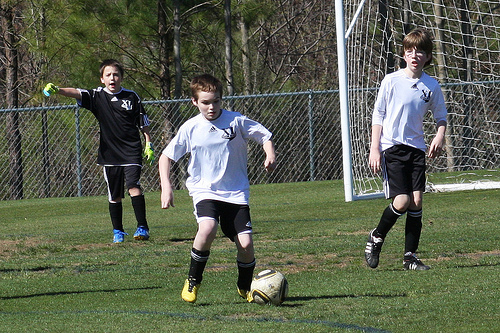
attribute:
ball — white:
[245, 265, 289, 306]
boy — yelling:
[168, 83, 286, 305]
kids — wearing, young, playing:
[65, 34, 455, 313]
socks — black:
[196, 240, 250, 292]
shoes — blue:
[97, 219, 156, 250]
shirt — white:
[162, 120, 268, 214]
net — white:
[347, 5, 498, 191]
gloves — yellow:
[38, 76, 68, 109]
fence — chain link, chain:
[19, 97, 346, 190]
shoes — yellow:
[178, 277, 259, 316]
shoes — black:
[353, 234, 433, 282]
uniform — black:
[81, 83, 169, 252]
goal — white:
[337, 10, 499, 201]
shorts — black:
[98, 164, 150, 199]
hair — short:
[190, 78, 223, 94]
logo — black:
[216, 123, 238, 147]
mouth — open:
[412, 56, 418, 70]